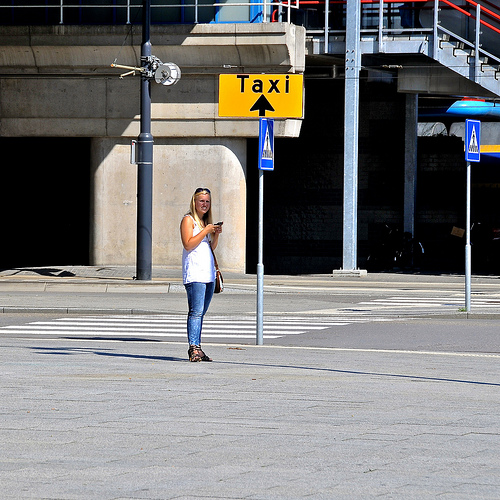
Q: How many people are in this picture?
A: One.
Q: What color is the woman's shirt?
A: White.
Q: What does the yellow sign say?
A: TAXI.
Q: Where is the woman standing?
A: On the sidewalk.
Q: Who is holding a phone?
A: The woman.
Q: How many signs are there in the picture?
A: Three.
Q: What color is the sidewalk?
A: Gray.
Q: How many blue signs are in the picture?
A: Two.